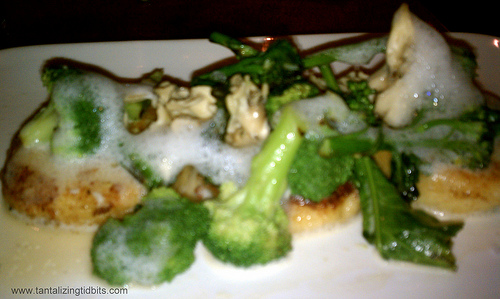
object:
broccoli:
[198, 122, 310, 297]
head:
[192, 192, 281, 258]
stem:
[242, 122, 311, 191]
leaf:
[368, 196, 441, 250]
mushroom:
[215, 83, 273, 132]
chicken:
[3, 164, 145, 258]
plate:
[32, 36, 492, 291]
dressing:
[375, 36, 450, 104]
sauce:
[433, 171, 480, 181]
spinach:
[325, 148, 427, 294]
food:
[23, 178, 92, 260]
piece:
[257, 134, 313, 248]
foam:
[161, 117, 219, 166]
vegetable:
[172, 149, 207, 165]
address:
[0, 281, 150, 296]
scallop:
[23, 131, 137, 217]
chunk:
[363, 17, 420, 68]